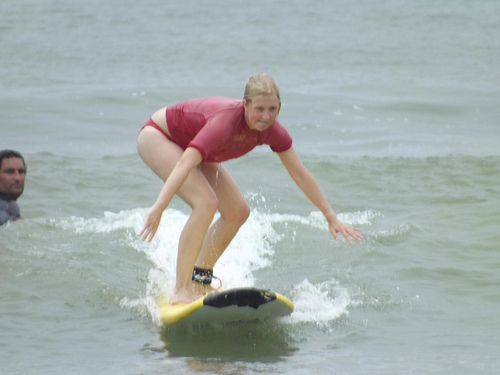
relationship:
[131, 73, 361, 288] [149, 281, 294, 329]
girl riding on surfboard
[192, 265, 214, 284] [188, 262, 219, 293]
ankle around ankle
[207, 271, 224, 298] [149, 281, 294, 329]
rope attached to surfboard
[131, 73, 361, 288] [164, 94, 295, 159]
girl wearing shirt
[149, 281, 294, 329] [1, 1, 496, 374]
surfboard floating in ocean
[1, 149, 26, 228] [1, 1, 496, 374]
man in ocean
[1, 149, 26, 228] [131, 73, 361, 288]
man looking at girl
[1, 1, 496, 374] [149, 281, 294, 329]
ocean breaking behind surfboard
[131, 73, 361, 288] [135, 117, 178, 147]
girl has bathing suit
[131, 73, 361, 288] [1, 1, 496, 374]
girl surfing in ocean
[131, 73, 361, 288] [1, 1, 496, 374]
girl in ocean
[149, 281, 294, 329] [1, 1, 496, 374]
surfboard in ocean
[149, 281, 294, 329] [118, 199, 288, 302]
surfboard creating wave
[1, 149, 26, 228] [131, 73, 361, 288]
man watching girl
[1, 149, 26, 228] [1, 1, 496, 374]
man standing in ocean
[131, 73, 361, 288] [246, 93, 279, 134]
girl has face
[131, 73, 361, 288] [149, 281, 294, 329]
girl standing on surfboard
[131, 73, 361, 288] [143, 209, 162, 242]
girl has hand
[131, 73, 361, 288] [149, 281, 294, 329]
girl balancing on surfboard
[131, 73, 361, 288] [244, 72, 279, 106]
girl has hair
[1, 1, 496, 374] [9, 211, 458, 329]
ocean has wave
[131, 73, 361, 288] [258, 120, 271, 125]
girl biting lip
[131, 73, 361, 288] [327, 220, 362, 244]
girl has hand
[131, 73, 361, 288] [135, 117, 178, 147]
girl wearing bathing suit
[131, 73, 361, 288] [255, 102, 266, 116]
girl has eye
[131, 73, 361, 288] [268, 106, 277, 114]
girl has eye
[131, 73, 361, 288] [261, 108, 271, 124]
girl has nose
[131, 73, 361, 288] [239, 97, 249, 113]
girl has right ear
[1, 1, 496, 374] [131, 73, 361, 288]
ocean beneath girl